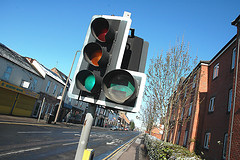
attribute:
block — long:
[0, 112, 181, 158]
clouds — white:
[217, 15, 237, 32]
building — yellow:
[0, 78, 40, 116]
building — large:
[178, 47, 239, 134]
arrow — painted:
[106, 134, 121, 146]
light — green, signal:
[75, 71, 135, 108]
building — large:
[166, 59, 208, 151]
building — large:
[147, 50, 236, 148]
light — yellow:
[72, 9, 158, 127]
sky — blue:
[183, 2, 221, 32]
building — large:
[198, 11, 239, 157]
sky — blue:
[0, 0, 238, 131]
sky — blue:
[16, 6, 58, 35]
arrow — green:
[107, 78, 135, 101]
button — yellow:
[84, 149, 94, 158]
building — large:
[196, 36, 238, 156]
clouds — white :
[26, 40, 71, 68]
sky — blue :
[1, 1, 234, 82]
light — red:
[91, 18, 114, 43]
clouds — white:
[37, 39, 68, 59]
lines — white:
[0, 138, 77, 155]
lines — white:
[18, 130, 81, 133]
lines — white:
[101, 131, 143, 158]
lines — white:
[1, 121, 65, 126]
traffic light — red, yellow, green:
[65, 13, 148, 113]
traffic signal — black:
[67, 7, 150, 115]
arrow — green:
[107, 77, 134, 97]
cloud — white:
[152, 34, 174, 47]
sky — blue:
[136, 2, 229, 29]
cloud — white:
[9, 27, 35, 42]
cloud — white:
[13, 6, 35, 19]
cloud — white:
[52, 53, 65, 60]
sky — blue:
[150, 2, 222, 34]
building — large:
[156, 18, 239, 155]